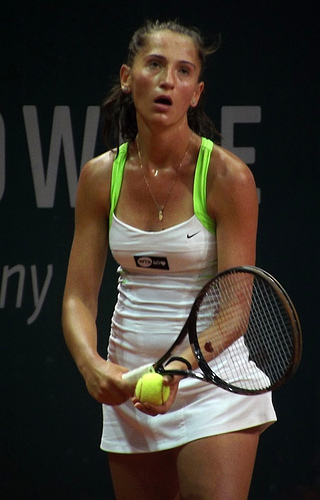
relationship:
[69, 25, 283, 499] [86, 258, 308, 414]
woman holding racket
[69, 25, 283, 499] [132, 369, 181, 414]
woman holding ball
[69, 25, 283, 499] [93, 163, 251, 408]
woman in dress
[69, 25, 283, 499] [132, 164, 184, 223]
woman wearing chain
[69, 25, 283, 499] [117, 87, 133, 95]
woman wearing earrings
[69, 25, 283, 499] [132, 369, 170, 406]
woman playing ball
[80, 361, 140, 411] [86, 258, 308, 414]
hand holds racket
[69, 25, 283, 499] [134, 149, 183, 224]
woman wears necklace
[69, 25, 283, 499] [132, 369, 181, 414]
woman holds ball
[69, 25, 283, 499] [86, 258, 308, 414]
woman holds racket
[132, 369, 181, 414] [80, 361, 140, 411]
ball in hand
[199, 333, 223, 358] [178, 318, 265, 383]
tattoo on forearm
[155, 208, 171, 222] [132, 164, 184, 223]
charm on chain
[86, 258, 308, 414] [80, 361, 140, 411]
racket in hand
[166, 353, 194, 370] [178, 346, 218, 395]
bracelet on wrist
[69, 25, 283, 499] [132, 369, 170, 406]
lady playing ball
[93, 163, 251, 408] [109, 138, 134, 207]
dress has green strap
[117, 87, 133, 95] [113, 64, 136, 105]
earrings in ear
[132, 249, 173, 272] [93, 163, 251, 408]
logo on dress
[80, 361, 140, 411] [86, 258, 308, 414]
hand holding racket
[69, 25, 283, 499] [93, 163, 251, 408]
woman wearing dress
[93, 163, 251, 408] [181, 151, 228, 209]
dress has strap